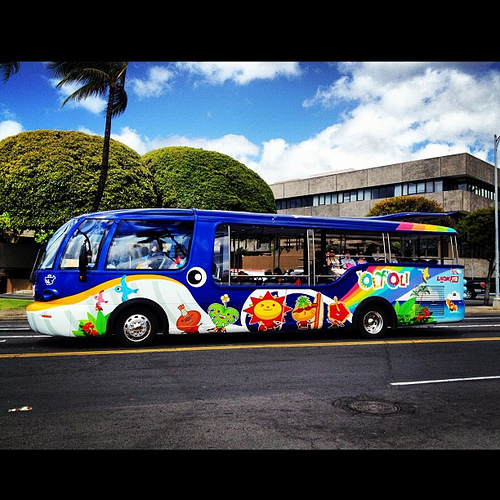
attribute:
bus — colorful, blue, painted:
[24, 207, 468, 347]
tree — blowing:
[45, 62, 131, 211]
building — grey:
[268, 154, 499, 290]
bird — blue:
[112, 272, 139, 304]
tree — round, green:
[145, 145, 279, 214]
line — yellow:
[1, 336, 500, 362]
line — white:
[390, 375, 499, 385]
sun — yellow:
[242, 291, 293, 332]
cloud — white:
[175, 63, 309, 88]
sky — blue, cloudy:
[1, 62, 499, 183]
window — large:
[211, 222, 308, 290]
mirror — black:
[78, 249, 89, 282]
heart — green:
[207, 302, 240, 332]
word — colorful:
[353, 270, 411, 291]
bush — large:
[0, 130, 157, 228]